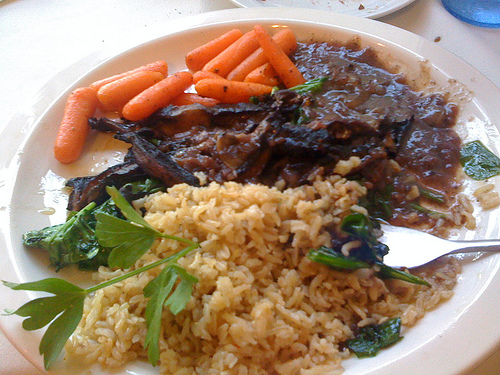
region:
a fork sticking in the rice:
[331, 198, 498, 278]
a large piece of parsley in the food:
[12, 191, 191, 374]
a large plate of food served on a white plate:
[6, 15, 497, 365]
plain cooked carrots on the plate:
[38, 18, 305, 158]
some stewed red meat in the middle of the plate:
[78, 111, 388, 201]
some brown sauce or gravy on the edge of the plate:
[293, 26, 465, 176]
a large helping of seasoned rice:
[120, 191, 384, 369]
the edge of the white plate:
[6, 38, 58, 179]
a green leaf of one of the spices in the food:
[343, 308, 406, 355]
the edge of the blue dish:
[440, 0, 498, 29]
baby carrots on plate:
[44, 22, 335, 164]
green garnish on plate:
[20, 186, 237, 363]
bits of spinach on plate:
[287, 172, 414, 373]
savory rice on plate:
[56, 172, 421, 361]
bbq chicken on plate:
[52, 51, 466, 213]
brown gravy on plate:
[276, 25, 498, 221]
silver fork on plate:
[344, 198, 498, 275]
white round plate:
[0, 0, 499, 374]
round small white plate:
[237, 0, 427, 52]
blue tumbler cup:
[416, 0, 498, 32]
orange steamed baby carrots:
[98, 21, 293, 118]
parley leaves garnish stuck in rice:
[21, 198, 201, 366]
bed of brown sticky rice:
[211, 185, 286, 359]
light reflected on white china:
[18, 153, 71, 236]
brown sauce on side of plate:
[291, 37, 463, 190]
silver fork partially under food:
[350, 231, 491, 278]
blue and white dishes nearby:
[244, 0, 498, 28]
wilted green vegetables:
[322, 209, 384, 301]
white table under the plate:
[0, 17, 96, 89]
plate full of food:
[58, 67, 449, 368]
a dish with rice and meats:
[1, 17, 498, 372]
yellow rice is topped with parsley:
[9, 185, 374, 374]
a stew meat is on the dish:
[69, 44, 452, 216]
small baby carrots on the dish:
[55, 25, 299, 170]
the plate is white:
[8, 12, 499, 373]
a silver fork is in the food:
[376, 225, 499, 263]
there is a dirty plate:
[251, 0, 398, 15]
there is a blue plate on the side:
[441, 0, 499, 26]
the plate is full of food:
[2, 25, 494, 374]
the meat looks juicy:
[43, 95, 440, 229]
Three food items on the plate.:
[11, 11, 492, 366]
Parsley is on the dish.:
[4, 200, 214, 367]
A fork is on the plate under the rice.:
[347, 199, 499, 287]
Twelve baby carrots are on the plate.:
[51, 25, 311, 168]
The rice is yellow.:
[74, 180, 373, 367]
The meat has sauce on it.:
[143, 43, 454, 202]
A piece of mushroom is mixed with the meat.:
[210, 121, 264, 176]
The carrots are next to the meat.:
[59, 15, 312, 157]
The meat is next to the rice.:
[103, 40, 450, 209]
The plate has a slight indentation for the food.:
[5, 4, 496, 368]